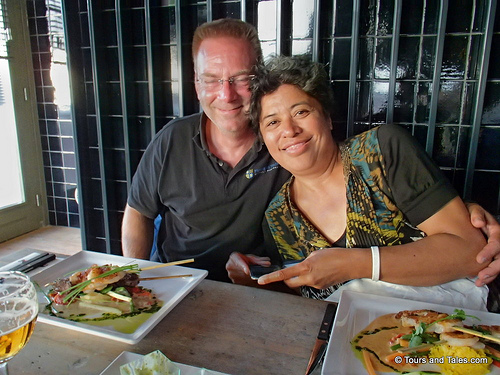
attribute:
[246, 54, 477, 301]
woman — white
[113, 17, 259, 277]
man — white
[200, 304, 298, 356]
table — wooden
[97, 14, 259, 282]
man — white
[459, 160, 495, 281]
arm — around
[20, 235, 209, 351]
plate — square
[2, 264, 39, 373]
glass — half full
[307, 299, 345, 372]
knife — a steak knife, black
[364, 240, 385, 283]
bracelet — white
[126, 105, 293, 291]
shirt — black, polo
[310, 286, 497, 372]
plate — white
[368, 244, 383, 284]
bracelet — white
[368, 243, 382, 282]
band — white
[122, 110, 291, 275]
shirt — gray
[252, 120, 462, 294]
top — green, yellow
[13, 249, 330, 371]
tabletop — wood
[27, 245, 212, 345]
plate — white, large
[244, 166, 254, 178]
logo — white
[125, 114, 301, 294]
shirt — gray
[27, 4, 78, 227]
tile — gray, white